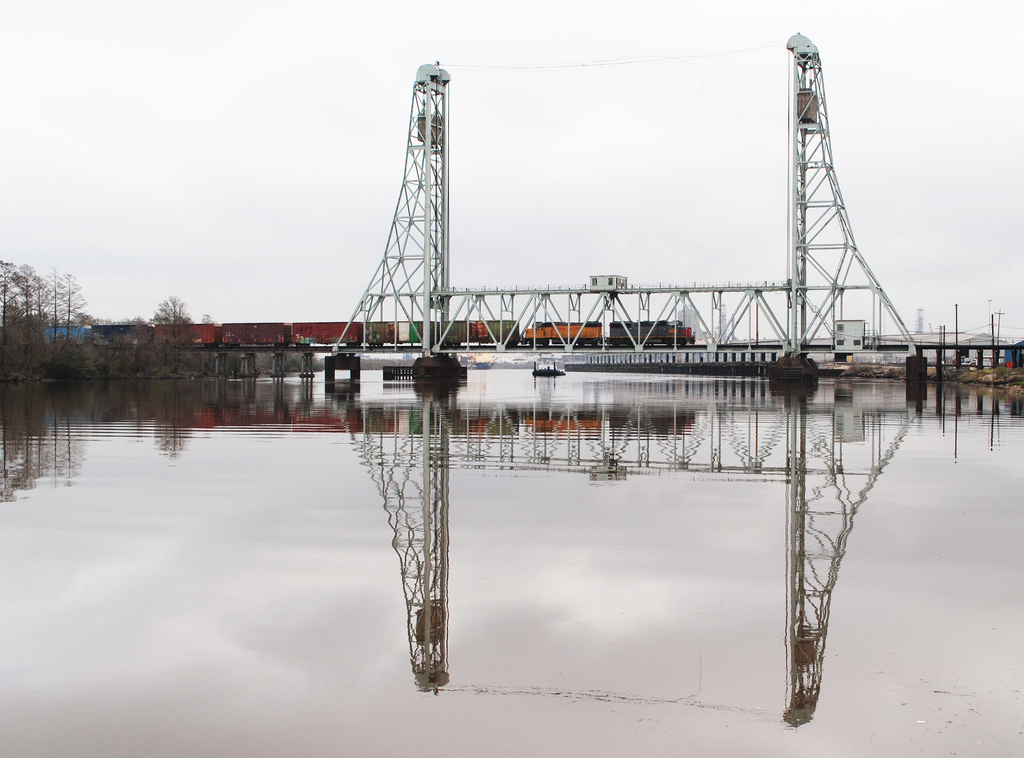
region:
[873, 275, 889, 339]
pole on the bridge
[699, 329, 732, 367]
pole on the bridge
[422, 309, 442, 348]
pole on the bridge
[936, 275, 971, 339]
pole on the bridge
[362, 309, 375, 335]
pole on the bridge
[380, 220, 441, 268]
pole on the bridge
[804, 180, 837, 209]
pole on the bridge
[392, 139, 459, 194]
pole on the bridge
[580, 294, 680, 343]
pole on the bridge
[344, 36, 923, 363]
The high bridge overpass.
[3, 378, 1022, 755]
The gray open lake.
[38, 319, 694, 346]
A locomotive on tracks.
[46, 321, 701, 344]
A long cargo locomotive.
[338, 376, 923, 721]
The bridge railings reflection.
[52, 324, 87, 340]
The locomotive's blue cargo trailer.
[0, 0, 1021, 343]
A cloudy day with an overcast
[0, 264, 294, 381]
The vegetation next to the bridge.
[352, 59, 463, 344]
The bridge pillar on the left.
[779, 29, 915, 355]
The bridge pillar on the right.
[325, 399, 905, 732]
the reflection of a bridge in the water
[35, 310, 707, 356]
a train crossing over a bridge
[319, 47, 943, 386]
a white bridge over a lake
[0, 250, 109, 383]
a few trees bare of leaves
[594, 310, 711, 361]
a dark blue train engine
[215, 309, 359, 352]
a pair of colorful train cars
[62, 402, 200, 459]
a few ripples in the water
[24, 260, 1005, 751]
a large, calm body of water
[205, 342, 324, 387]
rows of thick support pillars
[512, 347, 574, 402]
a small boat in the distance